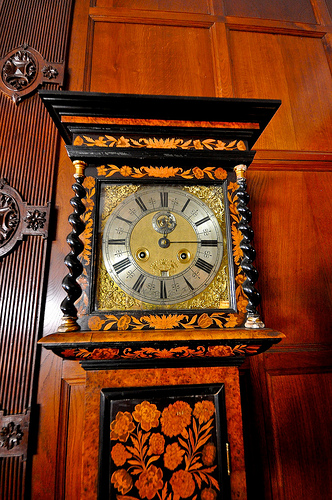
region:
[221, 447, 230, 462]
the handle is gold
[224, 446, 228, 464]
the handle is gold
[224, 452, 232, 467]
the handle is gold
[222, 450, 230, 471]
the handle is gold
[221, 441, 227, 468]
the handle is gold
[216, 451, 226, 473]
the handle is gold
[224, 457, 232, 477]
the handle is gold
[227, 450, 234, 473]
the handle is gold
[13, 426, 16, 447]
THE FLOWER IS CARVED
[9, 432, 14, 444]
THE FLOWER IS CARVED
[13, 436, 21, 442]
THE FLOWER IS CARVED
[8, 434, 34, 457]
THE FLOWER IS CARVED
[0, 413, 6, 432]
THE FLOWER IS CARVED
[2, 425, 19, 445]
THE FLOWER IS CARVED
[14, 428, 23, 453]
THE FLOWER IS CARVED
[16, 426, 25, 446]
THE FLOWER IS CARVED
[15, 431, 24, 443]
THE FLOWER IS CARVED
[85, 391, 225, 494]
flower design on clock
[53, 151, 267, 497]
large wood grandfather clock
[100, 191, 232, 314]
clock has gold and silver face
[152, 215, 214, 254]
clock has black hands and writing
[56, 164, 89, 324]
clock has spiral design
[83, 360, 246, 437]
light brown wood frame around floral design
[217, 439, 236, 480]
brass colored hinge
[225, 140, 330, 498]
wood panel wall behind clock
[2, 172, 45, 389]
intricate wood carving on wall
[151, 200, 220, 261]
clock reads 12:15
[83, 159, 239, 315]
this is a clock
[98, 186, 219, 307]
the clock is silvery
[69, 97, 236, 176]
the frame is wooden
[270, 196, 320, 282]
the board is wooden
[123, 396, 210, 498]
flowers are drawn on the board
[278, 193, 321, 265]
the board is brown in color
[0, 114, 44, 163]
the board is new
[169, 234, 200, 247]
the minute is long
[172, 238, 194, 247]
the minute hand is thin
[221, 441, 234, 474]
this is a hinge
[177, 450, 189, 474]
THE FLOWERS ARE DRAWN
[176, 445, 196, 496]
THE FLOWERS ARE DRAWN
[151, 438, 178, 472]
THE FLOWERS ARE DRAWN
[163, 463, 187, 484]
THE FLOWERS ARE DRAWN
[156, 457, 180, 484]
THE FLOWERS ARE DRAWN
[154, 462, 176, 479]
THE FLOWERS ARE DRAWN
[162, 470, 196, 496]
THE FLOWERS ARE DRAWN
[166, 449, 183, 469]
THE FLOWERS ARE DRAWN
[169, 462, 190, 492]
THE FLOWERS ARE DRAWN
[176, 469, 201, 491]
THE FLOWERS ARE DRAWN